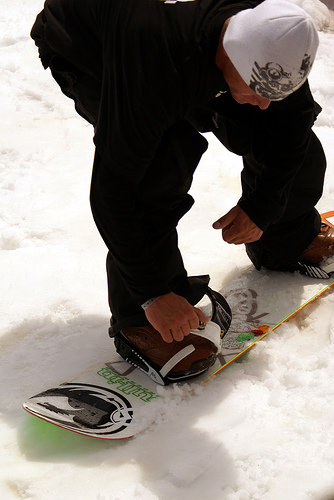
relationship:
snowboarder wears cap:
[34, 3, 332, 365] [224, 2, 319, 102]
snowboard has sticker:
[27, 204, 334, 441] [28, 384, 127, 434]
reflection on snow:
[1, 311, 259, 499] [3, 3, 329, 495]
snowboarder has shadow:
[34, 3, 332, 365] [1, 311, 259, 499]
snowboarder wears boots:
[34, 3, 332, 365] [125, 311, 214, 371]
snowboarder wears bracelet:
[34, 3, 332, 365] [140, 289, 167, 316]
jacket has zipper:
[51, 1, 284, 229] [210, 88, 224, 100]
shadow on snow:
[1, 311, 259, 499] [3, 3, 329, 495]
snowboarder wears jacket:
[34, 3, 332, 365] [51, 1, 284, 229]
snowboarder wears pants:
[34, 3, 332, 365] [40, 20, 186, 321]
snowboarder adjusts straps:
[34, 3, 332, 365] [155, 330, 220, 375]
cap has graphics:
[224, 2, 319, 102] [252, 51, 312, 96]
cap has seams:
[224, 2, 319, 102] [267, 13, 321, 52]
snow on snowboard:
[223, 265, 299, 321] [27, 204, 334, 441]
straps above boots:
[155, 330, 220, 375] [125, 311, 214, 371]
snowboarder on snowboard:
[34, 3, 332, 365] [27, 204, 334, 441]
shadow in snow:
[1, 311, 259, 499] [3, 3, 329, 495]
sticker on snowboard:
[28, 384, 127, 434] [27, 204, 334, 441]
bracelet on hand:
[140, 289, 167, 316] [146, 288, 209, 342]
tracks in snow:
[2, 37, 80, 245] [3, 3, 329, 495]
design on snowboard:
[95, 330, 257, 402] [27, 204, 334, 441]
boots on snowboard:
[125, 311, 214, 371] [27, 204, 334, 441]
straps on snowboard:
[155, 330, 220, 375] [27, 204, 334, 441]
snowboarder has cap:
[34, 3, 332, 365] [224, 2, 319, 102]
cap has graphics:
[224, 2, 319, 102] [248, 51, 315, 102]